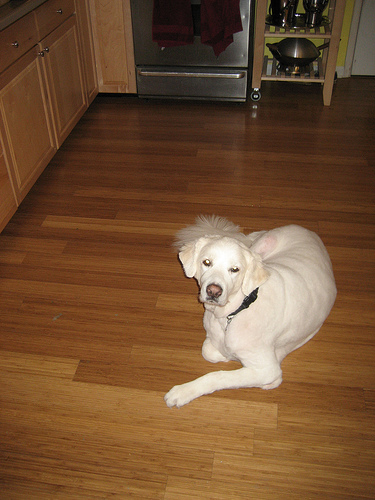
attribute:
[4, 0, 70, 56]
knobs — silver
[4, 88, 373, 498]
floor — wooden, dark, light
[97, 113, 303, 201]
boards — narrow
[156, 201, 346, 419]
dog — big, white, sitting, looking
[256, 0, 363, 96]
wall — yellow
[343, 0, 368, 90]
trim — white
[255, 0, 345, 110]
rack — wooden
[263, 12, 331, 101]
shelves — wooden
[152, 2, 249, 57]
towel — brown, red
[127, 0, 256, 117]
oven door — metal, stainless steel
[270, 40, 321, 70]
wok — metal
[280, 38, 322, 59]
lid — curved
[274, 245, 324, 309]
fur — smooth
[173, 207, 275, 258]
tail — fluffy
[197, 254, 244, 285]
eyes — dark, reflective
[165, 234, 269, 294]
ears — droopy, white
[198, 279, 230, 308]
nose — big, pink, tan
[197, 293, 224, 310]
mouth — small, angled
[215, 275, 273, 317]
collar — black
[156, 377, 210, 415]
paw — white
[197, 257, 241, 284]
camera flash — reflecting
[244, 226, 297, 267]
leg — white